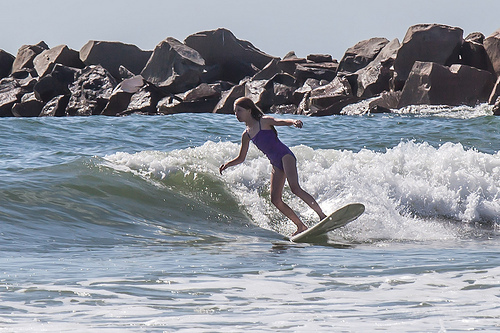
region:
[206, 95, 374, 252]
a young woman wearing a purple one-piece swimsuit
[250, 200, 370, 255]
white surfboard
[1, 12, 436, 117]
grey boulders in a breakwater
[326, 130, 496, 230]
surf from a breaking wave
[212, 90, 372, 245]
girl balancing on a surfboard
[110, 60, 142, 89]
large animal sitting on breakwater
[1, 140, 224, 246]
ocean wave starting to break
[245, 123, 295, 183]
purple one-piece swimsuit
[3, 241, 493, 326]
ocean wave petering out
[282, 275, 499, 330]
white seafom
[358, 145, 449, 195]
large white wave in water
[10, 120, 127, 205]
choppy blue waters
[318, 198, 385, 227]
tip of white surf board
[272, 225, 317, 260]
edge of surf board in water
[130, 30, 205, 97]
large gray rock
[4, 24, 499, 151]
cluster of different kinds of rocks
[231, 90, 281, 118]
long red hair on girl's head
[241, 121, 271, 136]
straps on girl's purple bathing suit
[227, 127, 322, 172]
girl's purple bathing suit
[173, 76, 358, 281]
girl balancing on surf board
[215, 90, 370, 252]
little girl surfing a wave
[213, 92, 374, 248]
young girl riding a surfboard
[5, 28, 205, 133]
large rocks making a sea wall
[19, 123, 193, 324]
crest of an ocean wave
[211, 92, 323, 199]
young girl in a purple bathing suit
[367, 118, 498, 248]
crashing ocean wave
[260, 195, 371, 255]
white surfboard on the ocean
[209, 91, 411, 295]
one person surfing a wave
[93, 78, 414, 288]
young girl surfing alone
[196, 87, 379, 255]
surfer girl in a purple swimsuit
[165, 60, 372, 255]
girl balancing on surfboard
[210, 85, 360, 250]
surfer holding arms out to side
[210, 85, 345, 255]
surfer with slightly bent knees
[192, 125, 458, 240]
white water churning behind surfer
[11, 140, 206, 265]
slope of smooth water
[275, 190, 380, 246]
surfer on white board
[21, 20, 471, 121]
surfer near row of boulders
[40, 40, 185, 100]
curved, flat and jagged edges of rocks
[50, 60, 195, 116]
light glistening off wet surfaces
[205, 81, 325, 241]
surfer wearing purple bathing suit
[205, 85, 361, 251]
Girl surfing in the sea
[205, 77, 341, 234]
Girl wearing a purple swimsuit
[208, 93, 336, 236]
Girl has arms extended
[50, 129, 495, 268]
Wave rolling in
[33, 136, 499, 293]
Waters are choppy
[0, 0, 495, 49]
Sky is blue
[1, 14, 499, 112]
Big rocks on the beach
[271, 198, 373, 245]
Surfboard is white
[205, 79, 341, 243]
Surfboard is inclined to the left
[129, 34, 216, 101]
Big rock